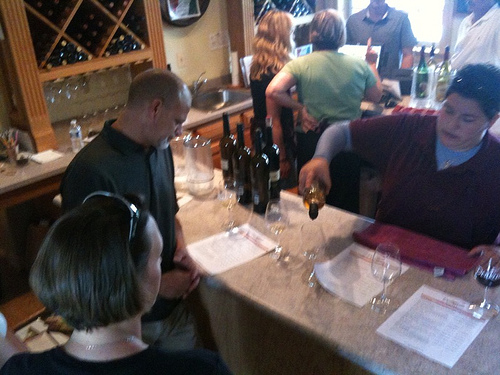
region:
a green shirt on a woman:
[288, 51, 379, 129]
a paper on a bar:
[378, 279, 498, 367]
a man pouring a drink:
[296, 62, 498, 274]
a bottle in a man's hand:
[300, 175, 330, 221]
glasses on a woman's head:
[78, 187, 144, 246]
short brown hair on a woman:
[26, 187, 156, 334]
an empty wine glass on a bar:
[364, 240, 406, 317]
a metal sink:
[185, 70, 257, 116]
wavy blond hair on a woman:
[247, 5, 296, 82]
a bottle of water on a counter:
[66, 115, 84, 154]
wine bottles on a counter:
[212, 116, 287, 217]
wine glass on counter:
[360, 248, 401, 303]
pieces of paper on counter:
[191, 223, 283, 270]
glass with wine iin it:
[474, 253, 494, 331]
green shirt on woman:
[280, 32, 371, 152]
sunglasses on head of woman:
[84, 182, 145, 246]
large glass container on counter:
[188, 135, 218, 182]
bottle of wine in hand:
[287, 162, 337, 244]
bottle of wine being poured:
[291, 153, 332, 218]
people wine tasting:
[54, 16, 458, 373]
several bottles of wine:
[208, 120, 291, 211]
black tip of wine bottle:
[304, 199, 324, 220]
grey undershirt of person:
[313, 118, 350, 162]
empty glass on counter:
[371, 242, 402, 305]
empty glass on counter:
[271, 218, 330, 292]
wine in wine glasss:
[469, 250, 499, 321]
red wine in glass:
[476, 253, 498, 304]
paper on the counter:
[388, 289, 495, 370]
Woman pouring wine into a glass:
[298, 165, 331, 243]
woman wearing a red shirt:
[355, 93, 499, 240]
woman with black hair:
[17, 186, 161, 330]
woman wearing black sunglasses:
[63, 188, 151, 266]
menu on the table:
[373, 279, 499, 374]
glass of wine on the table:
[473, 250, 495, 297]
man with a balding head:
[108, 58, 199, 156]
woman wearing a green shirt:
[278, 46, 372, 134]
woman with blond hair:
[241, 5, 302, 83]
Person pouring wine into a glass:
[296, 60, 498, 286]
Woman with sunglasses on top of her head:
[28, 187, 165, 369]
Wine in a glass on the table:
[468, 250, 498, 332]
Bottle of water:
[67, 116, 82, 157]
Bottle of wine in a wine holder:
[17, 3, 149, 68]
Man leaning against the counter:
[59, 70, 203, 328]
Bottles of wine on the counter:
[412, 42, 454, 102]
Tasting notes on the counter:
[373, 280, 494, 369]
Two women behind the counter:
[252, 7, 384, 164]